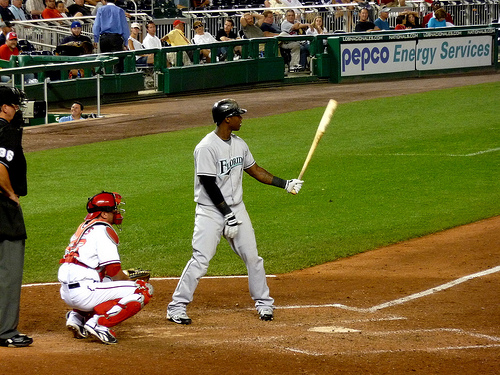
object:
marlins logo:
[218, 156, 245, 177]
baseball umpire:
[1, 87, 33, 354]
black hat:
[0, 85, 27, 105]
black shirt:
[0, 118, 28, 199]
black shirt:
[58, 33, 95, 51]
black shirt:
[215, 28, 238, 41]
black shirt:
[354, 20, 375, 32]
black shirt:
[259, 21, 282, 33]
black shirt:
[406, 18, 420, 28]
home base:
[306, 320, 365, 339]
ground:
[392, 148, 459, 196]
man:
[216, 16, 244, 63]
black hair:
[145, 21, 158, 30]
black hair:
[224, 18, 235, 27]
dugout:
[15, 96, 130, 134]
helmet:
[87, 190, 124, 225]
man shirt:
[92, 1, 130, 51]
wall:
[165, 57, 280, 96]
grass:
[34, 89, 495, 281]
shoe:
[0, 333, 34, 347]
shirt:
[163, 29, 191, 47]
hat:
[172, 19, 185, 27]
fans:
[160, 19, 220, 63]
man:
[92, 3, 132, 74]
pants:
[99, 33, 126, 74]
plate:
[306, 323, 363, 334]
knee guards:
[96, 279, 154, 327]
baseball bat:
[286, 93, 342, 196]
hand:
[286, 179, 305, 194]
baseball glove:
[221, 210, 243, 241]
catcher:
[54, 188, 157, 345]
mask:
[113, 192, 125, 232]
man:
[0, 31, 20, 63]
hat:
[6, 31, 17, 40]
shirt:
[0, 42, 19, 61]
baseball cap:
[210, 97, 249, 123]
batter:
[164, 94, 303, 327]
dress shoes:
[0, 331, 35, 349]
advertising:
[336, 35, 495, 77]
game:
[0, 27, 497, 374]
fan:
[142, 20, 166, 65]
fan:
[258, 10, 303, 70]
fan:
[125, 21, 162, 63]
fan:
[427, 8, 449, 29]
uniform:
[54, 218, 154, 328]